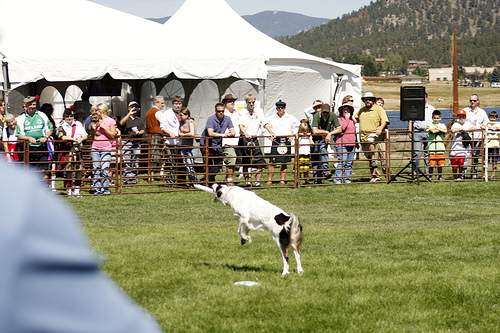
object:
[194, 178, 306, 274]
dog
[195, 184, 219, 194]
frisbee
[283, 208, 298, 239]
tail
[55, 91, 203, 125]
people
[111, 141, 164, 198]
fence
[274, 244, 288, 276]
leg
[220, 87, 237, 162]
man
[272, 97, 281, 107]
hat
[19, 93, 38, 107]
woman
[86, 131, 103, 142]
shirt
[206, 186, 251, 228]
goat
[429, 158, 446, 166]
shorts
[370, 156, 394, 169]
kilt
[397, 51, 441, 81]
houses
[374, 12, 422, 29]
mountain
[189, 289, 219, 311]
ground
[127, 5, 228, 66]
tent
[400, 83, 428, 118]
speaker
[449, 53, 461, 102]
pole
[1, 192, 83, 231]
shoulder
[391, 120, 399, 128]
water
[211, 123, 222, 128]
jacket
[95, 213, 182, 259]
grass